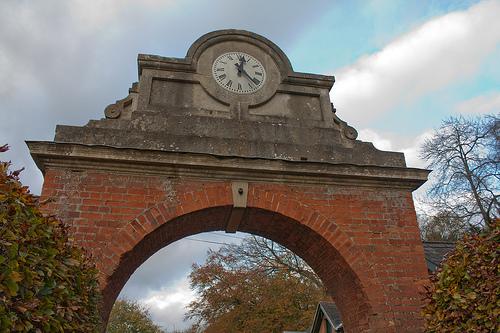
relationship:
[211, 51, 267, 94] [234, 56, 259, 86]
clock with hands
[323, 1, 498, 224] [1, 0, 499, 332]
clouds in sky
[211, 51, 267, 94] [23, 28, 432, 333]
clock on top of structure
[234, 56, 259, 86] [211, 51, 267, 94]
hands on clock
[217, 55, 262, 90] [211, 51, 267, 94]
numerals of clock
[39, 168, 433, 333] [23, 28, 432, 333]
arch of structure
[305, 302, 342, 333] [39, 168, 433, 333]
roof in middle of arch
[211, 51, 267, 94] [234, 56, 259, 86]
clock has hands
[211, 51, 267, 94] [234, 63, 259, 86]
clock has hand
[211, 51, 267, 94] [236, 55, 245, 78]
clock has hand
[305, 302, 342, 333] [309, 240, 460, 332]
roof of house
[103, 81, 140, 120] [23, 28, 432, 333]
scrollwork on structure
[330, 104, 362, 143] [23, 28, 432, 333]
scrollwork on structure